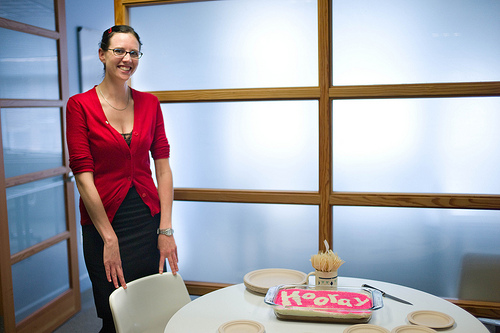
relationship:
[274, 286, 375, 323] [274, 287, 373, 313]
cake has frosting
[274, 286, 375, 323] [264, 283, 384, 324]
cake in pan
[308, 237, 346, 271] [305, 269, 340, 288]
forks in mug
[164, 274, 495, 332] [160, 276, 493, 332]
table has tablecloth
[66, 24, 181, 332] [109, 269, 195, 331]
woman behind chair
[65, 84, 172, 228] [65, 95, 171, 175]
cardigan has sleeves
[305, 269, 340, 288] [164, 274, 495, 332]
mug on top of table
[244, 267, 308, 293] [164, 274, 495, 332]
plates on top of table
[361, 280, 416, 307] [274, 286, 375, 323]
knife next to cake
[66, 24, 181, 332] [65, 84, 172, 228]
woman wearing cardigan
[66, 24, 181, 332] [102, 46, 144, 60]
woman wearing glasses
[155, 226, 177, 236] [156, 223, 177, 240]
watch on wrist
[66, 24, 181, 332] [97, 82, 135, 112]
woman wearing necklace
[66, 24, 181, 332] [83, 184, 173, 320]
woman wearing dress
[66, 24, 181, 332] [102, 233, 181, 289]
woman has hands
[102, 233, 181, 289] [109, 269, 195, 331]
hands touching chair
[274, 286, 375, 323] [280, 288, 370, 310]
cake has word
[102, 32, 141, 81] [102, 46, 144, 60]
face has glasses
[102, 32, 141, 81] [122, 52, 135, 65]
face has nose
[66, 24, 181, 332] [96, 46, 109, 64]
woman has ear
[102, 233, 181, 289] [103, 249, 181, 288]
hands has fingers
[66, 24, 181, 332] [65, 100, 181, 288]
woman has arms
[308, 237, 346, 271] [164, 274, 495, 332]
forks to top of table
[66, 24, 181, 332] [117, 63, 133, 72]
woman has teeth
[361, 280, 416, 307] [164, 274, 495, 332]
knife on top of table